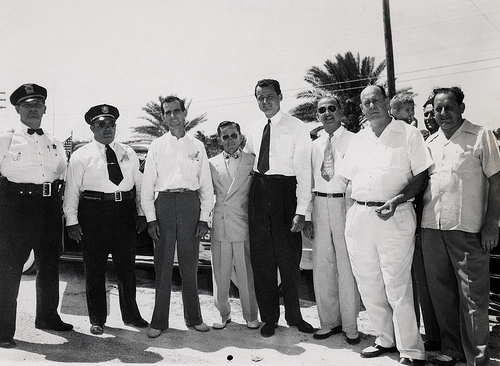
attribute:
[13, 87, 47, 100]
cap — here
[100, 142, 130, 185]
tie — black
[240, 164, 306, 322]
slacks — black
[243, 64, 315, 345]
man — tall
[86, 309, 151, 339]
shoes — black, white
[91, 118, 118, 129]
sunglasses — here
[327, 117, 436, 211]
shirt — white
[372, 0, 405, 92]
pole — wooden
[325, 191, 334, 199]
belt buckle — here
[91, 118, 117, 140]
face of man — here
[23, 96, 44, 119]
face of man — here